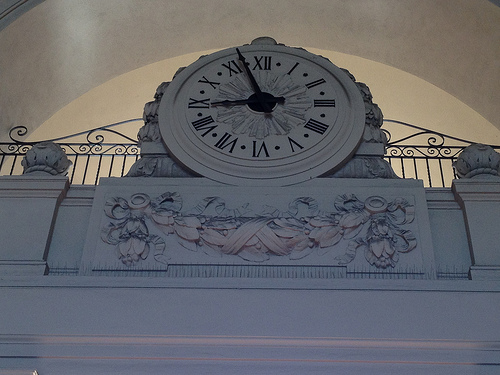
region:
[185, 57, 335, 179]
white clock on building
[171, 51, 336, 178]
white face on clock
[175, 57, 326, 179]
clock has roman numerals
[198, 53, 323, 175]
roman numerals are black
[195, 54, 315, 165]
clock hands are black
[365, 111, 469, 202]
black rail next to clock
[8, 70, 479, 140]
arch in white doorway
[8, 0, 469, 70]
tan wall above clock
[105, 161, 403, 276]
sculpture in wall under clock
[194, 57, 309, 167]
clock is reading 8:57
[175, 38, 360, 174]
this is a clock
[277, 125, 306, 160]
this is a number on the clock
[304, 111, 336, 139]
this is a number on the clock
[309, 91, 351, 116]
this is a number on the clock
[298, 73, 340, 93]
this is a number on the clock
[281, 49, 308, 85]
this is a number on the clock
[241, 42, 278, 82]
this is a number on the clock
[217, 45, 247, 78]
this is a number on the clock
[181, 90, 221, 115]
this is a number on the clock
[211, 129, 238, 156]
this is a number on the clock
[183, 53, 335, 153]
black roman numerals on clock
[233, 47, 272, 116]
black minute hand on the clock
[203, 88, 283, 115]
black hour hand on the clock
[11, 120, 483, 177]
railing on both sides of the clock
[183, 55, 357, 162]
white face of the clock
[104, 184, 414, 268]
ornate carving below the clock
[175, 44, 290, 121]
clock hands showing 8:56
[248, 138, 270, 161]
roman number six on the clock face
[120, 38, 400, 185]
white frame of the clock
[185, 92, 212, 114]
roman numeral nine on the clock face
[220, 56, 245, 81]
The Roman Numeral is black.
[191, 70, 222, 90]
The Roman Numeral is black.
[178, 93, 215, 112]
The Roman Numeral is black.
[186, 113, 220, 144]
The Roman Numeral is black.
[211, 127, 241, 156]
The Roman Numeral is black.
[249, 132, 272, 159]
The Roman Numeral is black.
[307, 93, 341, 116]
The Roman Numeral is black.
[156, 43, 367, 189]
A clock on a building.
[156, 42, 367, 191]
A white round clock.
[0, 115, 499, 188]
Black railing on a building.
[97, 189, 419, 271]
Decorations on a wall.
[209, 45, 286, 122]
Hands on a clock.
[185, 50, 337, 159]
Numbers on a clock.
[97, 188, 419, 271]
Flowers on a wall.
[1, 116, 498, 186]
Metal railing by a clock.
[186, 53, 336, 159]
Roman numerals on a clock.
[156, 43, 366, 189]
A clock with numbers.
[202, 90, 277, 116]
hour hand on a clock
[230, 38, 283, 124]
minute hand on a clock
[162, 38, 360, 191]
face of a clock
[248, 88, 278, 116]
dial on a clock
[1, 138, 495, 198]
rail behind a clock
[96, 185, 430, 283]
design under a clock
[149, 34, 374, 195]
round face of a clock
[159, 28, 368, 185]
large clock front of rail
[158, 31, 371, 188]
white clock in front of rail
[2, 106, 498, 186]
railing behind large clock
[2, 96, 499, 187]
railing behind clock is metal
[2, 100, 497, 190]
railing behind clock is black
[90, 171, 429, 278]
decorative painting under clock